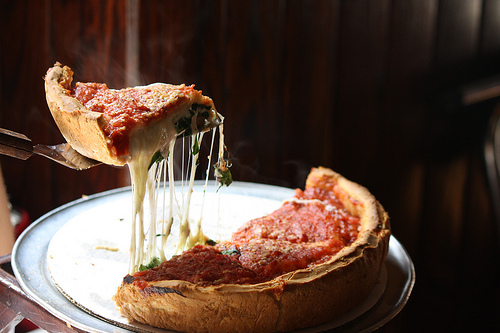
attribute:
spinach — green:
[177, 101, 235, 188]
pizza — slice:
[115, 165, 394, 326]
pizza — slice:
[42, 63, 214, 166]